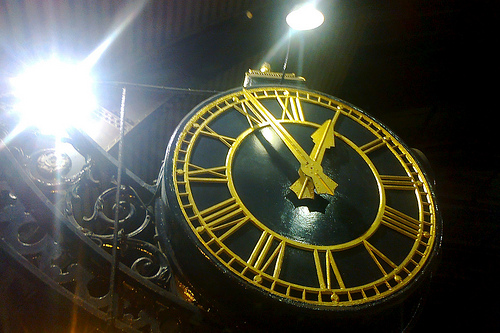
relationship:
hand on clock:
[291, 116, 339, 207] [156, 62, 452, 329]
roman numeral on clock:
[275, 93, 305, 123] [156, 62, 452, 329]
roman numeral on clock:
[196, 121, 237, 153] [156, 62, 452, 329]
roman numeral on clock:
[376, 199, 426, 242] [156, 62, 452, 329]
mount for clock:
[1, 90, 196, 332] [156, 62, 452, 329]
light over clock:
[287, 2, 324, 34] [156, 62, 452, 329]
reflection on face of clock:
[284, 198, 323, 240] [156, 62, 452, 329]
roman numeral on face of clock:
[275, 93, 305, 123] [156, 62, 452, 329]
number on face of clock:
[357, 130, 387, 156] [156, 62, 452, 329]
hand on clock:
[241, 89, 341, 202] [156, 62, 452, 329]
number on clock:
[357, 130, 387, 156] [156, 62, 452, 329]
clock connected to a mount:
[156, 62, 452, 329] [1, 90, 196, 332]